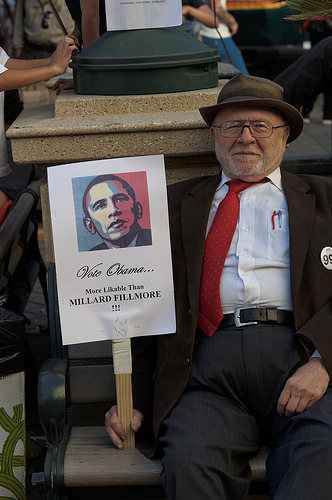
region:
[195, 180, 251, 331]
A red tie.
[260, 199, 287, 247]
Two ink pens in shirt pocket.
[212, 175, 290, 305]
A man's white dress shirt.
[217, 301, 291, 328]
Black belt with silver buckle.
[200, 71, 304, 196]
A man with a pair of glasses.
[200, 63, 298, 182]
A man with a hat on his head.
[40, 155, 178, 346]
A white square poster.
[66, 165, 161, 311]
An image of Obama.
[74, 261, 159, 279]
The statement Vote Obama...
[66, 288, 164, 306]
The name MILLARD FILLIMORE.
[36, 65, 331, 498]
Man holds a banner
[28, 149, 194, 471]
Banner is white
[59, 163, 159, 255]
Picture on banner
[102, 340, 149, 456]
Handle of banner is brown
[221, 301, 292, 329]
Strap is black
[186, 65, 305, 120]
Hat is black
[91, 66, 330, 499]
Man sits on a bench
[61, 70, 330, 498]
Man wears a brown jacket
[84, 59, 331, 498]
Man wears a long sleeve shirt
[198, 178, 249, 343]
Tie is red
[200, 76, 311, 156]
Man wearing hat on head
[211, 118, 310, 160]
Glasses on man's face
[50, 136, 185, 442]
Man holding white sign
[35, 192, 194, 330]
White sign says vote obama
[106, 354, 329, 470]
Man sitting on bench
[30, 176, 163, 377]
Bench is in front of concrete pillar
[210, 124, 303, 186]
Gray beard on man's face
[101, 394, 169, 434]
Man holding sign in right hand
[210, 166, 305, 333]
Man has on red tie on neck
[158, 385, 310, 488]
Man wearing dark pants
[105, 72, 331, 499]
man holding a sign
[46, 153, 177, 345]
sign being held by man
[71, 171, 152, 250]
drawing of President Obama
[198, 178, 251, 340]
red necktie on seated man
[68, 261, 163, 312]
lettering on sign encouraging votes for Obama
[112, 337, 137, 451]
stick attached to sign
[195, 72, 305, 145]
hat being worn by man sitting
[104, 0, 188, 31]
part of posted sign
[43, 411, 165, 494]
bench on which man is sitting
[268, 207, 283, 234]
ink pens in man's shirt pocket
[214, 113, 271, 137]
an old man's speck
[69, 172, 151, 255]
picture of obama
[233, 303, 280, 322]
part of the belt's backal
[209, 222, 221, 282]
part of a red tie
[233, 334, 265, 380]
part of a trouser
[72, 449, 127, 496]
lower part of a bench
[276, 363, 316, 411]
left hand of the man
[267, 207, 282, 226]
two pens on the shirt pocket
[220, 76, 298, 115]
the old man's hat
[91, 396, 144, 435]
right hand of the old man